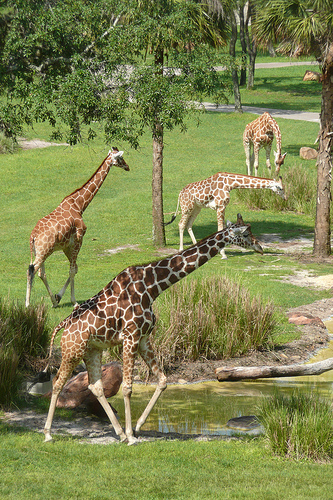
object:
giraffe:
[24, 145, 130, 309]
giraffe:
[243, 110, 288, 176]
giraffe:
[161, 172, 288, 252]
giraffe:
[43, 212, 264, 446]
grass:
[234, 165, 315, 215]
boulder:
[51, 364, 123, 408]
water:
[107, 376, 333, 434]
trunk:
[152, 130, 166, 247]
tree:
[0, 2, 246, 247]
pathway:
[126, 98, 321, 124]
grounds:
[0, 45, 332, 497]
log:
[215, 356, 333, 381]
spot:
[143, 265, 155, 286]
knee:
[121, 384, 133, 398]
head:
[230, 212, 265, 257]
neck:
[144, 227, 228, 300]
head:
[272, 148, 288, 174]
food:
[254, 170, 315, 212]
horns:
[236, 212, 244, 224]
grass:
[270, 408, 332, 464]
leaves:
[131, 72, 188, 134]